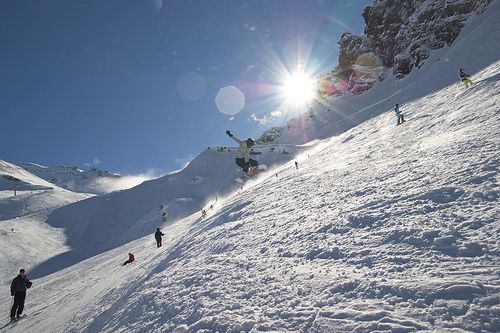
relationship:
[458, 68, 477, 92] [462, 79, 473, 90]
person wearing pants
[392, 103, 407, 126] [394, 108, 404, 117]
person wearing coat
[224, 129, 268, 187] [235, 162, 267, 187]
person jumping on snowboard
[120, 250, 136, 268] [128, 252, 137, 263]
person in jacket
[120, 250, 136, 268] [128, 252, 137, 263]
person sitting in jacket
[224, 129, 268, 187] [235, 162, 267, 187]
person on snowboard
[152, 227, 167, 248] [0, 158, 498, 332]
person standing in snow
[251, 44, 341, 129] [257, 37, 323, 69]
sun with flares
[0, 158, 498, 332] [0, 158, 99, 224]
snow covered hill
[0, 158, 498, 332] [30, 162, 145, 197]
snow covered hill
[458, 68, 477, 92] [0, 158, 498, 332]
person in snow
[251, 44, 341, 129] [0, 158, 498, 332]
sun shining on snow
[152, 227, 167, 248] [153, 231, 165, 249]
person in clothing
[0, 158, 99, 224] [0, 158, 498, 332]
hill in snow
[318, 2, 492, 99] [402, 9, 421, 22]
trees covered in snow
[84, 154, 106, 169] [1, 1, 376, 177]
clouds in sky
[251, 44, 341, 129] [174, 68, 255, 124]
sun producing a glare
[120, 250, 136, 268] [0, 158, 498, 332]
person sitting in snow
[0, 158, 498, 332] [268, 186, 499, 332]
snow has tracks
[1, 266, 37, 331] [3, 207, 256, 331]
skier on slope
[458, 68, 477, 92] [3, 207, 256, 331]
person on a slope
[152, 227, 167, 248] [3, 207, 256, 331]
person on a slope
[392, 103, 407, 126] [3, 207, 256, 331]
person on a slope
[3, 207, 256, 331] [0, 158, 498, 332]
slope has snow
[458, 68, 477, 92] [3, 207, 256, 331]
person on slope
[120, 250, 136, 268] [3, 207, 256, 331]
person on a slope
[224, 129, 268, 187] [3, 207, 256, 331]
person on a slope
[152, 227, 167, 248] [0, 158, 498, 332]
person standing on snow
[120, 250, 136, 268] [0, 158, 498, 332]
person sitting on snow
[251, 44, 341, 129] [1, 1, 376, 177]
sun in sky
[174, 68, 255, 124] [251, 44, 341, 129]
glare of sun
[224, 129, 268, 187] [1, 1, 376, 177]
person in sky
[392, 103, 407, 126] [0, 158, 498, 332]
person in snow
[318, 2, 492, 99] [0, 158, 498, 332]
trees covered in snow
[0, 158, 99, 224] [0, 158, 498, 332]
hill covered in snow